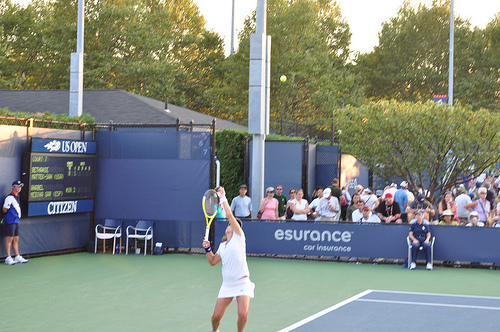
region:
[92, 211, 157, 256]
Two empty chairs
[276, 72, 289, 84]
Tennis ball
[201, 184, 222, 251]
Tennis raquet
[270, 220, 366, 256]
An advertisement on the partition between court and audience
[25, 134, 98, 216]
The score board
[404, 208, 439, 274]
Line judge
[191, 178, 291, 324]
A female tennis player wearing white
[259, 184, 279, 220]
Woman spectator in a pink top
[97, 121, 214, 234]
Tall fence surrounding the tennis courts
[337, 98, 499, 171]
Tree in among the spectators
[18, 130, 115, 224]
US Open scoreboard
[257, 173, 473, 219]
people watching tennis match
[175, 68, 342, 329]
tennis player with racquet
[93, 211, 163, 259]
two empty blue and white chairs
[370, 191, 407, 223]
man in red hat watching tennis match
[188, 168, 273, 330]
female tennis player with white outfit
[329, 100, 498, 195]
one tree with leaves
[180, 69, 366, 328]
player getting ready to hit tennis ball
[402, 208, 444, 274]
referee sitting in chair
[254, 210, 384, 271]
advertisement for company at tennis match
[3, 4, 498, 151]
a line of trees in the background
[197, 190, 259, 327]
the tennis player on the court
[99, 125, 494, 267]
the fence next to the tennis court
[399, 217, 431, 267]
the referee watching the game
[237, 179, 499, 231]
the audience watching the game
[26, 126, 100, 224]
the scoreboard for the game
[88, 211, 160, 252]
the chairs sitting in the corner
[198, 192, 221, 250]
the racket in the player's hand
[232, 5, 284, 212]
the pole by the fence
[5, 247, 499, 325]
the tennis court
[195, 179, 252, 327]
A tennis player about to hit a tennis ball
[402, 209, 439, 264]
a man in blue clothing sitting in a chair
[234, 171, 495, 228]
a crowd of people watching a tennis match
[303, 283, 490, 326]
a tennis court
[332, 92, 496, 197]
a tree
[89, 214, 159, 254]
two blue and white chairs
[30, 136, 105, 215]
a scoreboard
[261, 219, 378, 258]
an advertisement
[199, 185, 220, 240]
the womans tennis racket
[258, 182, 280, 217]
a woman in a pink shirt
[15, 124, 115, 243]
Scoreboard on the side of court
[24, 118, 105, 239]
Scoreboard with name of tournament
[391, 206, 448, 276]
linesman sitting on chair beside court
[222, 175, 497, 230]
spectators watching tennis match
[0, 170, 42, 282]
Ballboy standing next to electronic scoreboard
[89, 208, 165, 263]
Two empty chairs beside court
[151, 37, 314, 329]
Tennis player about to hit ball in the air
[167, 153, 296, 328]
tennis player holding racquet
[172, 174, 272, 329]
Tennis player wearing skirt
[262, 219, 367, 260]
advertising on barrier on side of court